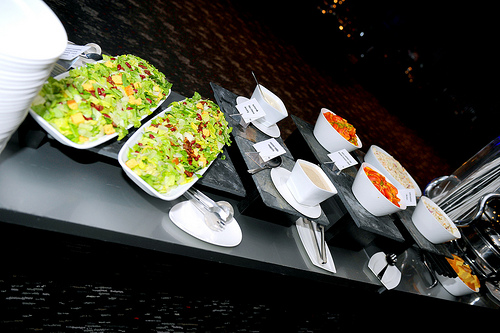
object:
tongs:
[303, 214, 331, 267]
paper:
[326, 149, 357, 169]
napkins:
[309, 216, 335, 264]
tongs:
[173, 187, 236, 232]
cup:
[293, 159, 340, 195]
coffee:
[296, 156, 338, 194]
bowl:
[250, 85, 289, 127]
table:
[6, 60, 499, 305]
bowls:
[313, 107, 362, 153]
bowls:
[356, 143, 422, 207]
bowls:
[410, 196, 462, 244]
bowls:
[284, 157, 339, 207]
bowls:
[249, 83, 289, 126]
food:
[29, 52, 237, 195]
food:
[361, 165, 403, 208]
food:
[363, 149, 416, 206]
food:
[422, 199, 456, 236]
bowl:
[311, 104, 363, 158]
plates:
[0, 1, 67, 161]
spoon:
[375, 250, 397, 282]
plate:
[367, 250, 404, 290]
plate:
[170, 199, 242, 246]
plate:
[300, 218, 340, 269]